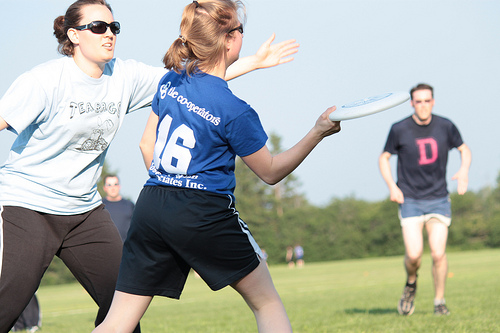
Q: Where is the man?
A: In the background.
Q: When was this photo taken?
A: During a frisbee game.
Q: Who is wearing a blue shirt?
A: The blonde woman.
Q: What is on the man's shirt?
A: The letter D.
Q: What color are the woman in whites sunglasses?
A: Black.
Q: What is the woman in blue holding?
A: A frisbee.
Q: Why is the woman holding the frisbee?
A: To throw.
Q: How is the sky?
A: Clear and sunny.